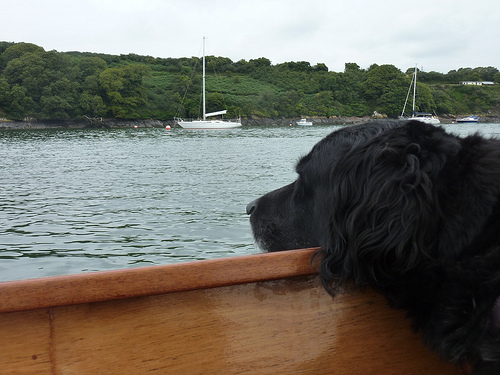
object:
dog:
[244, 115, 499, 374]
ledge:
[0, 245, 334, 314]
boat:
[5, 242, 464, 374]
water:
[0, 124, 498, 281]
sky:
[0, 0, 500, 76]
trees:
[0, 41, 48, 70]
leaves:
[60, 89, 68, 90]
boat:
[176, 31, 246, 128]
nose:
[242, 194, 267, 222]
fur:
[240, 118, 499, 375]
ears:
[323, 144, 443, 289]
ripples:
[0, 189, 264, 287]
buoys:
[164, 124, 171, 130]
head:
[245, 113, 450, 286]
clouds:
[0, 0, 499, 75]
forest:
[0, 39, 499, 118]